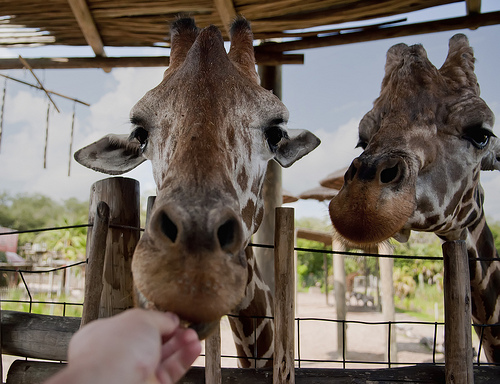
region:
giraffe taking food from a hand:
[34, 21, 289, 381]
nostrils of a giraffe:
[151, 204, 251, 256]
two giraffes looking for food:
[86, 10, 498, 370]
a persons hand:
[47, 299, 204, 382]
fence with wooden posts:
[11, 181, 445, 381]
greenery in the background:
[26, 184, 447, 304]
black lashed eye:
[460, 114, 498, 151]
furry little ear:
[64, 116, 153, 178]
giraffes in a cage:
[42, 14, 498, 361]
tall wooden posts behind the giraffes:
[324, 231, 410, 363]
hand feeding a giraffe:
[39, 305, 199, 382]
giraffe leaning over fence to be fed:
[72, 20, 320, 377]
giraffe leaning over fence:
[328, 32, 498, 374]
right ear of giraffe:
[72, 134, 150, 173]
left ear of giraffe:
[269, 126, 320, 168]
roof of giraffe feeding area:
[1, 2, 499, 68]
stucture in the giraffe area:
[286, 161, 398, 370]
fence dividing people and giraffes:
[2, 206, 499, 382]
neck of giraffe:
[436, 172, 498, 369]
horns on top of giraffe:
[165, 9, 262, 81]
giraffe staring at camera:
[76, 30, 300, 381]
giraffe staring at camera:
[341, 28, 498, 290]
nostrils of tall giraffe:
[142, 202, 256, 271]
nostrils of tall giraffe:
[328, 154, 413, 199]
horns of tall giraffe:
[152, 2, 272, 89]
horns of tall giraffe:
[364, 25, 476, 81]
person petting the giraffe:
[84, 315, 220, 373]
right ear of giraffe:
[258, 122, 310, 165]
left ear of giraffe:
[84, 131, 146, 176]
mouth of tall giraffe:
[321, 193, 424, 243]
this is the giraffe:
[323, 35, 487, 238]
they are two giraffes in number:
[131, 56, 497, 258]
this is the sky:
[314, 60, 394, 117]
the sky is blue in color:
[318, 71, 349, 91]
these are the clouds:
[20, 117, 57, 164]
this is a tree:
[18, 193, 43, 217]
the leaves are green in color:
[302, 256, 316, 275]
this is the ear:
[87, 126, 132, 156]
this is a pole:
[276, 207, 302, 359]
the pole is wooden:
[278, 199, 298, 293]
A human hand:
[49, 297, 193, 382]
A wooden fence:
[5, 232, 498, 381]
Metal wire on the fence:
[6, 255, 494, 382]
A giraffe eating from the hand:
[102, 22, 329, 382]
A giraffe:
[326, 27, 497, 309]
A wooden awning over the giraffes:
[1, 0, 497, 73]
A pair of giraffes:
[77, 15, 492, 381]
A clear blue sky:
[7, 30, 497, 241]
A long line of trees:
[10, 188, 496, 293]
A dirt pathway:
[31, 280, 488, 378]